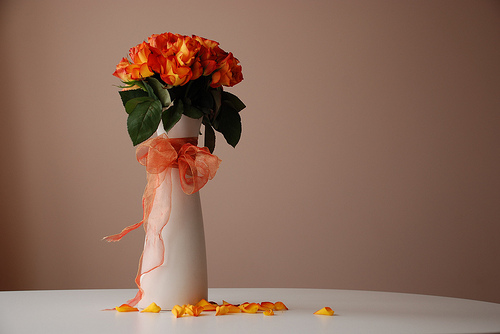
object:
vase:
[135, 112, 209, 312]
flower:
[206, 50, 244, 90]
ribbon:
[100, 132, 224, 311]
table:
[0, 289, 500, 333]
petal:
[310, 305, 335, 315]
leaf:
[124, 99, 162, 146]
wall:
[0, 1, 499, 302]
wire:
[101, 220, 144, 243]